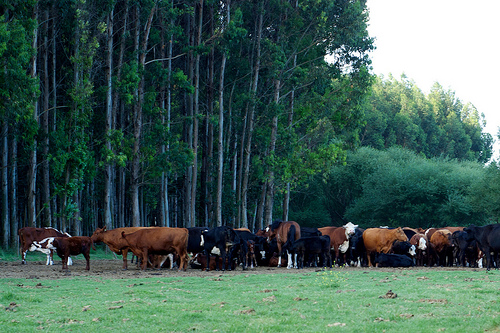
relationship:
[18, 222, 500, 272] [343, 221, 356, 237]
cow with face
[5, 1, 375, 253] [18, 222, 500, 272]
trees behind cow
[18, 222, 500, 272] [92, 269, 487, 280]
cow on dirt patch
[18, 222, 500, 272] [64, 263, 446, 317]
cow grazing on pasture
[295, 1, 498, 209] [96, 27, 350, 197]
tops of tree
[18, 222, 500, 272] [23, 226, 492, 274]
cow of cows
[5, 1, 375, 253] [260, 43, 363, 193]
trees with leaves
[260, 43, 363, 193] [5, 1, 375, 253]
leaves on trees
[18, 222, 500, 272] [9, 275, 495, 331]
cow on grass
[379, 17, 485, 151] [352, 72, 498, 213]
sun shining on trees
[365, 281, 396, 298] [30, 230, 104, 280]
excrement of cow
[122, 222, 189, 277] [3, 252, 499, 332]
cow stepping at grass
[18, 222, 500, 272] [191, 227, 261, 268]
cow are black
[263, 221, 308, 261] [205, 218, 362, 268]
horse at middle of cows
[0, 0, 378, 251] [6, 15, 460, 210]
trees at left side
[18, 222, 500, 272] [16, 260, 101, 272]
cow standing at ground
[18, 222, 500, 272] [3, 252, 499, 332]
cow on grass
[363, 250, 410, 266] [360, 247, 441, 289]
cow laying on grass